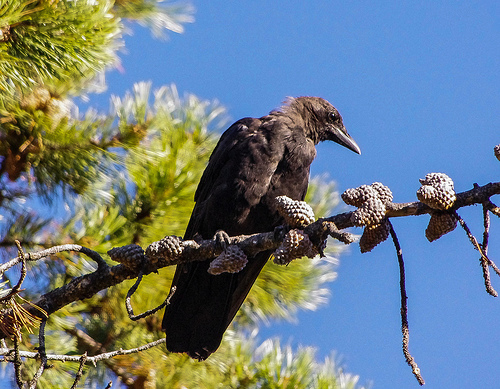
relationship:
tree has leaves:
[1, 1, 496, 387] [3, 1, 378, 387]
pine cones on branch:
[107, 144, 500, 276] [4, 181, 498, 343]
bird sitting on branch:
[161, 95, 362, 361] [4, 181, 498, 343]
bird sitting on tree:
[161, 95, 362, 361] [1, 1, 496, 387]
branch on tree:
[4, 181, 498, 343] [1, 1, 496, 387]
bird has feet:
[161, 95, 362, 361] [210, 222, 294, 253]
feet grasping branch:
[210, 222, 294, 253] [4, 181, 498, 343]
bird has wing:
[161, 95, 362, 361] [160, 117, 308, 360]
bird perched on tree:
[161, 95, 362, 361] [1, 1, 496, 387]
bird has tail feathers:
[161, 95, 362, 361] [160, 236, 276, 362]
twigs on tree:
[1, 201, 496, 388] [1, 1, 496, 387]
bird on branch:
[161, 95, 362, 361] [4, 181, 498, 343]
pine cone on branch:
[106, 242, 147, 270] [4, 181, 498, 343]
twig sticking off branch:
[386, 217, 426, 385] [4, 181, 498, 343]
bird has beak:
[161, 95, 362, 361] [328, 126, 363, 154]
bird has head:
[161, 95, 362, 361] [286, 94, 363, 156]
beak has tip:
[328, 126, 363, 154] [350, 141, 361, 155]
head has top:
[286, 94, 363, 156] [299, 94, 341, 123]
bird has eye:
[161, 95, 362, 361] [329, 111, 340, 121]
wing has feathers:
[160, 117, 308, 360] [157, 116, 308, 361]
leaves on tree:
[3, 1, 378, 387] [1, 1, 496, 387]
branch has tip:
[4, 181, 498, 343] [454, 142, 500, 298]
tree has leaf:
[1, 1, 496, 387] [16, 294, 50, 318]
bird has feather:
[161, 95, 362, 361] [192, 115, 262, 203]